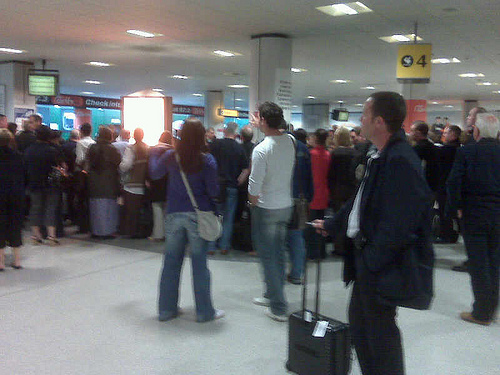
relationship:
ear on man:
[374, 115, 384, 131] [333, 80, 443, 370]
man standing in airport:
[310, 91, 436, 375] [0, 0, 500, 375]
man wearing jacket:
[310, 91, 436, 375] [325, 147, 433, 306]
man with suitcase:
[334, 101, 473, 373] [275, 295, 354, 373]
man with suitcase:
[310, 91, 436, 375] [284, 210, 359, 374]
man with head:
[442, 111, 497, 328] [468, 105, 499, 145]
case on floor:
[285, 222, 350, 374] [102, 341, 281, 367]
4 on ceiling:
[415, 53, 430, 73] [297, 6, 397, 82]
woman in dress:
[85, 124, 123, 239] [85, 142, 123, 237]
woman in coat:
[85, 124, 123, 239] [83, 140, 124, 203]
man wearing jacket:
[246, 102, 295, 322] [356, 132, 435, 315]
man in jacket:
[310, 91, 436, 375] [338, 127, 436, 311]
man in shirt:
[251, 100, 294, 322] [242, 132, 302, 209]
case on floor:
[284, 305, 351, 373] [0, 242, 500, 375]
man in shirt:
[243, 99, 297, 323] [245, 135, 295, 211]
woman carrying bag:
[148, 118, 225, 323] [172, 147, 222, 240]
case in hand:
[285, 222, 350, 374] [304, 210, 335, 240]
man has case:
[310, 91, 436, 375] [285, 222, 350, 374]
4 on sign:
[417, 54, 427, 67] [395, 42, 433, 83]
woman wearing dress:
[85, 124, 123, 243] [88, 137, 122, 234]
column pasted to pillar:
[277, 69, 291, 111] [247, 35, 292, 142]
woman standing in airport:
[148, 118, 225, 323] [0, 0, 497, 372]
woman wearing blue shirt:
[148, 118, 225, 323] [145, 145, 225, 215]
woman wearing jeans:
[148, 118, 225, 323] [153, 207, 219, 324]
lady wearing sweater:
[300, 125, 340, 227] [306, 138, 334, 208]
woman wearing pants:
[28, 99, 293, 302] [2, 176, 29, 256]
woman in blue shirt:
[148, 118, 225, 323] [149, 146, 221, 212]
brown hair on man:
[365, 92, 405, 134] [310, 91, 436, 375]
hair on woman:
[177, 116, 212, 173] [138, 106, 275, 323]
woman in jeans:
[148, 118, 225, 323] [157, 214, 217, 324]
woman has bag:
[148, 118, 225, 323] [168, 190, 288, 272]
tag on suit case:
[313, 315, 328, 340] [280, 213, 351, 372]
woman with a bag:
[148, 118, 225, 323] [172, 147, 223, 242]